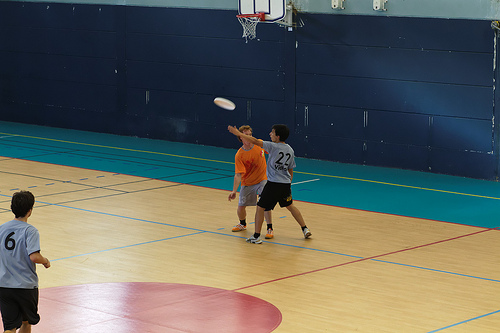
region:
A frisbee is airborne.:
[215, 97, 236, 110]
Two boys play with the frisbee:
[223, 122, 314, 243]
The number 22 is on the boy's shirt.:
[275, 151, 291, 166]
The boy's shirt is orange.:
[234, 143, 266, 185]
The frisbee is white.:
[211, 96, 236, 111]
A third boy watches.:
[0, 189, 48, 331]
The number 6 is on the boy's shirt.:
[2, 230, 17, 248]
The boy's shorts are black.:
[257, 180, 292, 212]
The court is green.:
[347, 163, 498, 229]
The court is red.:
[146, 283, 213, 332]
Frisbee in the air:
[210, 93, 240, 113]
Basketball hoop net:
[236, 19, 261, 41]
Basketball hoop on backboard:
[236, 11, 268, 21]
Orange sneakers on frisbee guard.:
[225, 221, 278, 241]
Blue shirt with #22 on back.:
[264, 143, 298, 185]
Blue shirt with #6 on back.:
[2, 222, 42, 291]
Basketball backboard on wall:
[233, 2, 288, 24]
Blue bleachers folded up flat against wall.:
[2, 0, 498, 185]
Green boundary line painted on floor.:
[0, 129, 499, 201]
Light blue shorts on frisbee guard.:
[234, 183, 269, 205]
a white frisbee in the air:
[210, 93, 235, 115]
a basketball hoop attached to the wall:
[235, 0, 305, 44]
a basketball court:
[1, 117, 498, 332]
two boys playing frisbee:
[219, 117, 319, 249]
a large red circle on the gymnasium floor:
[0, 278, 296, 331]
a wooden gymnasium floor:
[1, 118, 499, 330]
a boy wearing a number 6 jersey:
[0, 185, 59, 332]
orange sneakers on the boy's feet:
[231, 220, 278, 239]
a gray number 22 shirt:
[258, 137, 303, 189]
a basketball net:
[236, 13, 264, 42]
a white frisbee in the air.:
[195, 80, 252, 120]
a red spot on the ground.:
[1, 260, 301, 331]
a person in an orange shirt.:
[224, 137, 272, 194]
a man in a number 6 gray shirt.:
[1, 211, 43, 288]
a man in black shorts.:
[235, 175, 300, 209]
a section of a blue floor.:
[0, 120, 497, 227]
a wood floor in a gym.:
[0, 123, 499, 329]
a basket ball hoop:
[221, 0, 298, 63]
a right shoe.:
[295, 226, 320, 247]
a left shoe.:
[234, 220, 266, 241]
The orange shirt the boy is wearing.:
[227, 141, 264, 189]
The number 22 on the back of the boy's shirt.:
[278, 150, 294, 163]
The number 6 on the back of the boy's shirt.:
[1, 225, 16, 245]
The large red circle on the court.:
[24, 252, 284, 329]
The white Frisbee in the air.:
[219, 92, 236, 109]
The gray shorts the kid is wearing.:
[234, 181, 270, 203]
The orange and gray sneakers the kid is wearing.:
[224, 213, 277, 237]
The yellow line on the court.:
[14, 128, 499, 219]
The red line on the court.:
[166, 204, 480, 296]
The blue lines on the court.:
[1, 127, 453, 331]